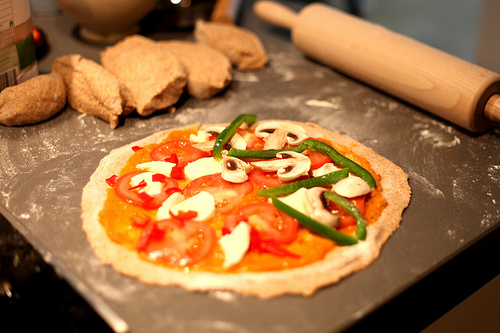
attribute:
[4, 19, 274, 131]
lumps — five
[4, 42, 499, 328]
surface — metal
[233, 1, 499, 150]
roller — dough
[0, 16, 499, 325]
surface — grey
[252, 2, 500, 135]
rolling pin — wooden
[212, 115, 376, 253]
pepper — green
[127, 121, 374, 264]
mushroom — slices, white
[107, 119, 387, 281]
tomatoes — slices, red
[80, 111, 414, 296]
pizza — uncooked, round, small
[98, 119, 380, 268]
sauce — red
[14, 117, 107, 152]
flour — white